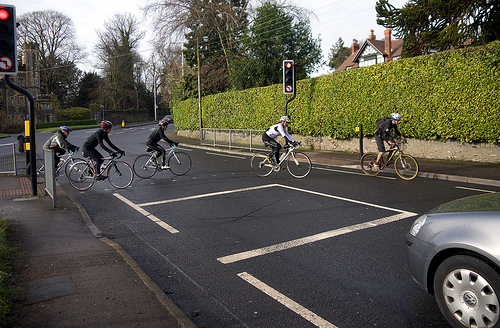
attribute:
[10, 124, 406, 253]
street — black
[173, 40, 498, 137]
hedge — green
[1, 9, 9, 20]
light — red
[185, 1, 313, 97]
trees — green, tall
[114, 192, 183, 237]
lines — white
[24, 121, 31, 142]
object — yellow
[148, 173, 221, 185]
spots — white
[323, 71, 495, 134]
shrubbery — green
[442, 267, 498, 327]
tire — silver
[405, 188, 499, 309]
car — silver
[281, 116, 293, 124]
helmet — silver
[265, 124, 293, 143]
shirt — white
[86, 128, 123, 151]
shirt — black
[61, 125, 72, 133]
helmet — blue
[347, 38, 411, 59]
building — stone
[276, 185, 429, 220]
marks — paint